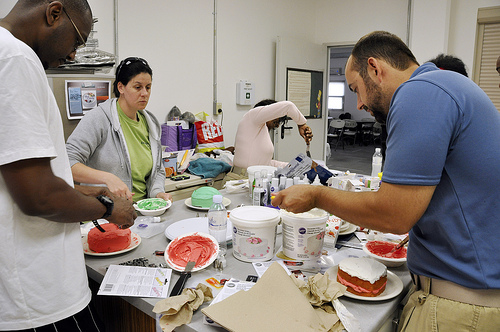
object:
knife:
[304, 128, 310, 153]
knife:
[170, 249, 203, 293]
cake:
[87, 223, 132, 254]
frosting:
[170, 236, 207, 262]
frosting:
[339, 257, 387, 285]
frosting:
[377, 243, 383, 252]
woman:
[233, 98, 315, 176]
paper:
[201, 262, 347, 331]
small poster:
[64, 79, 112, 120]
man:
[270, 29, 500, 332]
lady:
[64, 55, 172, 217]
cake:
[336, 257, 387, 298]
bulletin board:
[285, 66, 323, 120]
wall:
[0, 5, 315, 170]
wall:
[273, 0, 500, 172]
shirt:
[0, 28, 94, 332]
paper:
[97, 264, 173, 300]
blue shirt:
[379, 61, 499, 289]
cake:
[191, 186, 224, 208]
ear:
[45, 0, 64, 25]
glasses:
[60, 6, 87, 50]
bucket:
[229, 205, 280, 263]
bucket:
[279, 207, 330, 260]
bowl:
[133, 197, 172, 217]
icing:
[138, 198, 167, 210]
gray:
[82, 124, 107, 163]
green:
[116, 99, 152, 205]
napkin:
[151, 283, 214, 331]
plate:
[164, 231, 220, 272]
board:
[41, 62, 114, 140]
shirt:
[231, 100, 307, 169]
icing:
[191, 186, 221, 208]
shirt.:
[116, 101, 154, 205]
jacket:
[65, 97, 167, 205]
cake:
[312, 160, 329, 172]